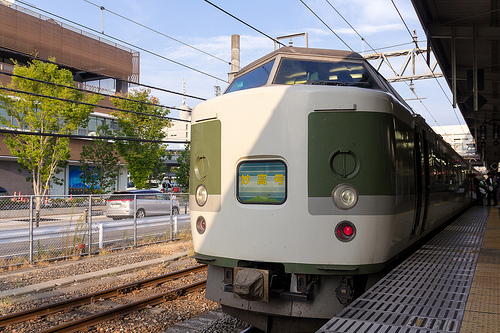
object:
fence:
[0, 192, 191, 268]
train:
[182, 43, 498, 333]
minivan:
[104, 189, 183, 220]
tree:
[0, 52, 105, 223]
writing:
[240, 172, 285, 186]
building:
[0, 1, 143, 205]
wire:
[387, 0, 463, 125]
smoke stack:
[229, 34, 240, 74]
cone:
[11, 191, 17, 201]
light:
[341, 224, 356, 237]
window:
[272, 55, 385, 91]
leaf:
[23, 102, 27, 105]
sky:
[0, 0, 500, 125]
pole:
[88, 195, 92, 255]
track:
[0, 263, 206, 333]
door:
[415, 132, 430, 237]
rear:
[106, 193, 132, 216]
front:
[191, 49, 387, 269]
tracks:
[238, 321, 254, 332]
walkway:
[319, 198, 499, 333]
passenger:
[478, 176, 487, 205]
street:
[0, 189, 194, 245]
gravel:
[0, 256, 210, 333]